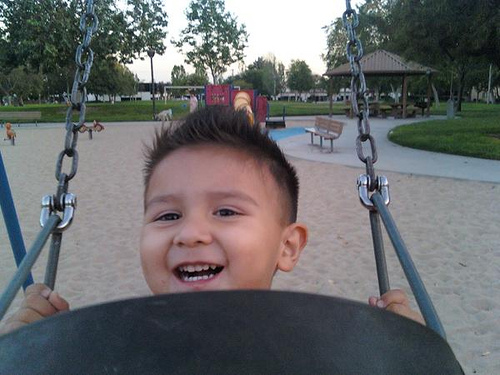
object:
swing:
[0, 0, 469, 375]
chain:
[344, 1, 398, 210]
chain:
[33, 2, 99, 227]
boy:
[2, 106, 426, 331]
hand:
[4, 282, 74, 344]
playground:
[2, 106, 499, 374]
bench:
[304, 117, 343, 153]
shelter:
[322, 49, 441, 119]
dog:
[155, 109, 172, 125]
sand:
[328, 187, 480, 281]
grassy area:
[393, 118, 497, 167]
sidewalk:
[278, 120, 500, 195]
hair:
[141, 104, 299, 199]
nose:
[173, 216, 213, 248]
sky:
[119, 2, 343, 77]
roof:
[323, 47, 439, 76]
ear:
[277, 223, 309, 272]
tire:
[1, 290, 469, 375]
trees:
[1, 0, 144, 69]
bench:
[2, 111, 41, 128]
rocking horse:
[66, 120, 105, 140]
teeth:
[175, 264, 220, 281]